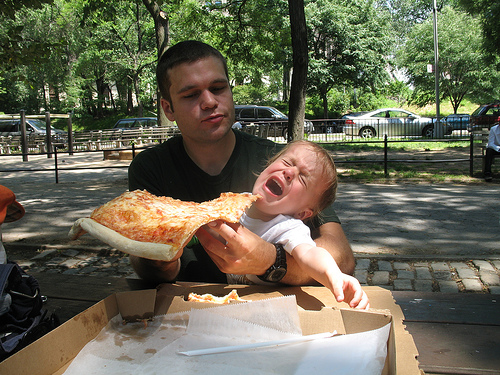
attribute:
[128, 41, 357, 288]
man — light skinned, seated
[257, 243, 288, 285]
watch — black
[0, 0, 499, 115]
leaves — green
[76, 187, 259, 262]
pizza — large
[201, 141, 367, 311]
child — crying, little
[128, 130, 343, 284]
shirt — black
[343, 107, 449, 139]
car — silver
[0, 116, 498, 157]
fence — metal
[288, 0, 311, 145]
tree — large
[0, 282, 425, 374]
box — empty, open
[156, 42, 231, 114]
hair — black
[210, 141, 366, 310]
person — sitting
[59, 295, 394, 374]
paper — white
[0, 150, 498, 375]
area — paved